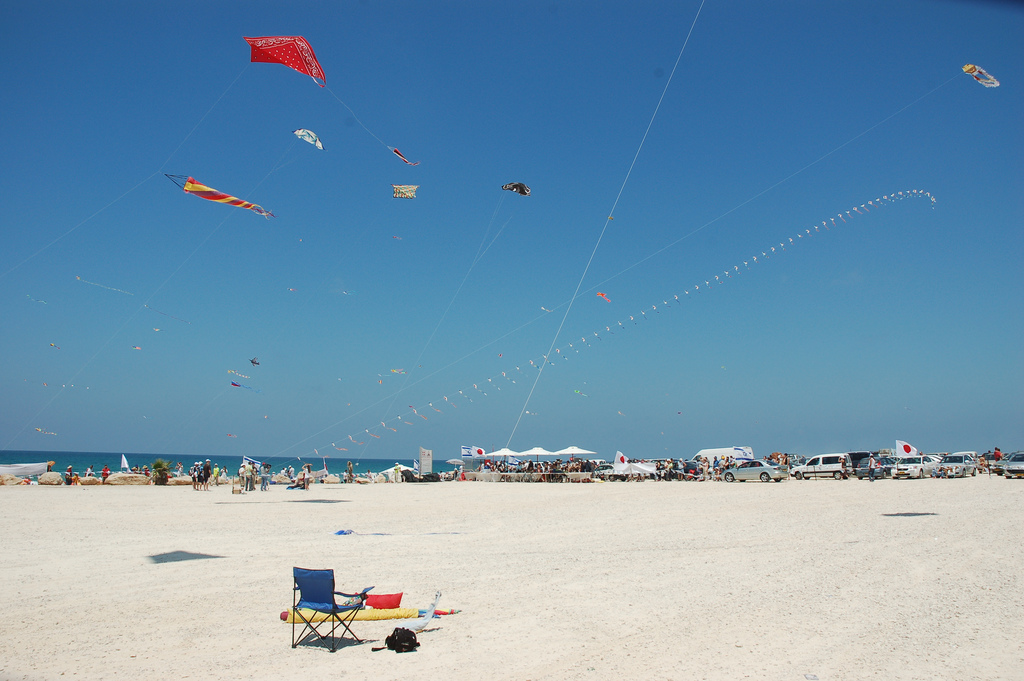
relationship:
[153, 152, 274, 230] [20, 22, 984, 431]
kite in air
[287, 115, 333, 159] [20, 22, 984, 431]
kite in air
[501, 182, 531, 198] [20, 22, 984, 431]
kite in air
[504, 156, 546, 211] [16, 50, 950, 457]
kite in air